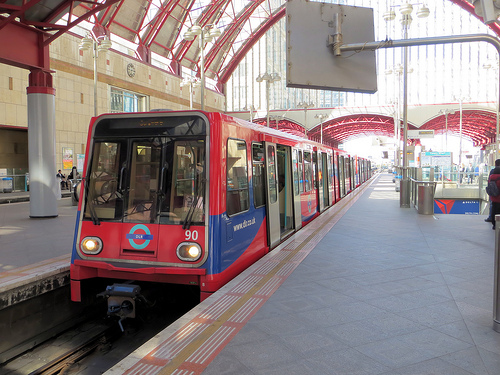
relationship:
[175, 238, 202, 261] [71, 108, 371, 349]
headlight on train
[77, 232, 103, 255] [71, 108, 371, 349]
headlight on train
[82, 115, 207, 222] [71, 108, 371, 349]
windshield on train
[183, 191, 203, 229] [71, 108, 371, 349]
windshield wiper on train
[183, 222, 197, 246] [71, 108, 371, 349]
9 on train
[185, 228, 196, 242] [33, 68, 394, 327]
0 on train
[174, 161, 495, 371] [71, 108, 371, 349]
walkway near train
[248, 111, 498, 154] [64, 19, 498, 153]
archways on ceiling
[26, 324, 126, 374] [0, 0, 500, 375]
track in train station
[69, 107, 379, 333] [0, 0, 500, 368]
train in train station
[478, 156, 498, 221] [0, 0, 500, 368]
person in train station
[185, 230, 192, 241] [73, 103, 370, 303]
9 on train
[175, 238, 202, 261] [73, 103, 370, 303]
headlight on train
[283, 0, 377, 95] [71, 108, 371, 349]
sign by train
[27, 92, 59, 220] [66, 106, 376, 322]
white pole by train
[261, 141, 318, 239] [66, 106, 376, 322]
door on train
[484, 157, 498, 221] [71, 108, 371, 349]
passenger walking from train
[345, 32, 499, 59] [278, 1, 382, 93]
pole attached to board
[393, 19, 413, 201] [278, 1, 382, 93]
pole attached to board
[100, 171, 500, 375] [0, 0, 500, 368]
walkway in train station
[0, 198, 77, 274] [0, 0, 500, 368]
walkway in train station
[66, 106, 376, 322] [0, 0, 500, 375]
train coming in train station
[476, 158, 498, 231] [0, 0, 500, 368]
person standing in train station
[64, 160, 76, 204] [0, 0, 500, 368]
person standing in train station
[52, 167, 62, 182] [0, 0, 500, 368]
person standing in train station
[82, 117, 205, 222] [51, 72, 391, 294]
window on train